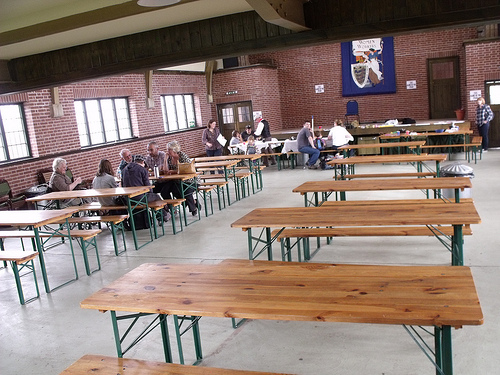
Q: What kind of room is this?
A: Cafeteria.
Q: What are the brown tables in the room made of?
A: Wood.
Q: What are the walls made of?
A: Brick.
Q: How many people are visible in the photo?
A: Fourteen.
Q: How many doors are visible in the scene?
A: Three.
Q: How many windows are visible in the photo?
A: Three.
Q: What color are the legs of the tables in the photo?
A: Green.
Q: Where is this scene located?
A: In a cafeteria.